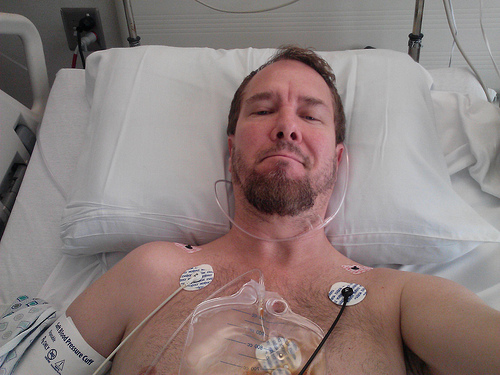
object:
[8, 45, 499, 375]
man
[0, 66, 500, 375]
hospital bed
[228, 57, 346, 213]
head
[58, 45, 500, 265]
pillow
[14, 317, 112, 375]
blood pressure cuff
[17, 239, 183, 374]
arm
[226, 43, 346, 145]
hair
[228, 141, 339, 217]
beard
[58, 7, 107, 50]
outlet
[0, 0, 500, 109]
wall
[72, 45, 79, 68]
cord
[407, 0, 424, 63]
bedpost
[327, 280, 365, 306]
medical patch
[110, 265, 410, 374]
chest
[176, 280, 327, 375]
medical bag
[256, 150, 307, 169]
mouth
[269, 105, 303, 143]
nose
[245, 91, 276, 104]
eyebrow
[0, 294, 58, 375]
hospital gown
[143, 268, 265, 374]
tube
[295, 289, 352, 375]
wire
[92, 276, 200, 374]
wire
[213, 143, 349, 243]
wire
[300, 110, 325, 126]
eye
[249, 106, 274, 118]
eye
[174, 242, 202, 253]
wire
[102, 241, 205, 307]
shoulder